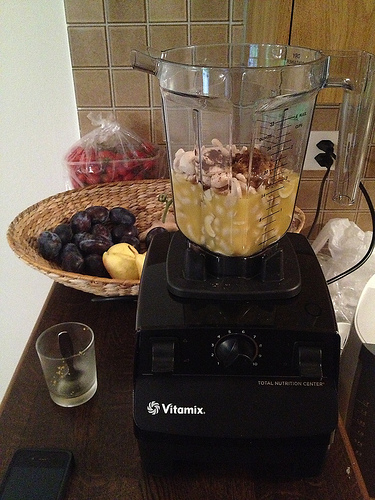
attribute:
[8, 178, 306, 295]
basket — light brown, wicker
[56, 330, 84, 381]
spoon — small 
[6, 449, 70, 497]
cellphone — black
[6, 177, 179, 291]
basket — wicker